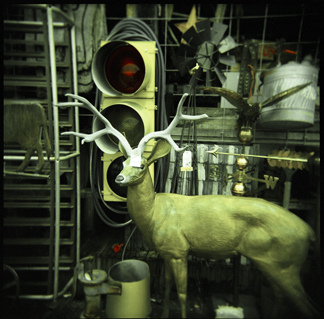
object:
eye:
[138, 162, 144, 168]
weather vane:
[203, 148, 321, 198]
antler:
[59, 92, 132, 158]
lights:
[106, 154, 127, 198]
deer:
[61, 92, 320, 318]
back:
[168, 192, 261, 216]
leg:
[161, 259, 173, 317]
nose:
[114, 174, 122, 181]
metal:
[44, 3, 81, 301]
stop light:
[91, 41, 147, 96]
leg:
[276, 270, 319, 318]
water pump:
[78, 264, 122, 318]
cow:
[3, 98, 50, 172]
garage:
[0, 0, 324, 319]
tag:
[128, 145, 142, 169]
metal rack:
[2, 3, 81, 301]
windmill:
[176, 22, 244, 87]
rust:
[109, 281, 124, 295]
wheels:
[0, 260, 19, 313]